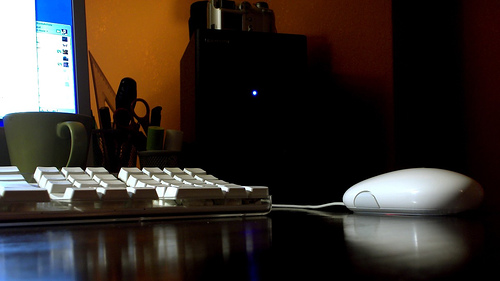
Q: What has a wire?
A: Mouse.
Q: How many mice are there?
A: One.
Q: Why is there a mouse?
A: To control computer.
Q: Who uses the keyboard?
A: Computer user.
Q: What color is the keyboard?
A: White.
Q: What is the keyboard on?
A: Desk.